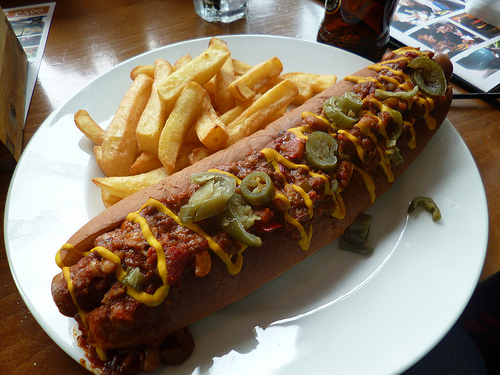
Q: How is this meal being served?
A: On plate.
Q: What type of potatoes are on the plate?
A: French fried.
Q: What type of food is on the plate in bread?
A: Hotdog.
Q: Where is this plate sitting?
A: On table.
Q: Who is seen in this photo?
A: Noone.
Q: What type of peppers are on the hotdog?
A: Jalpenos.